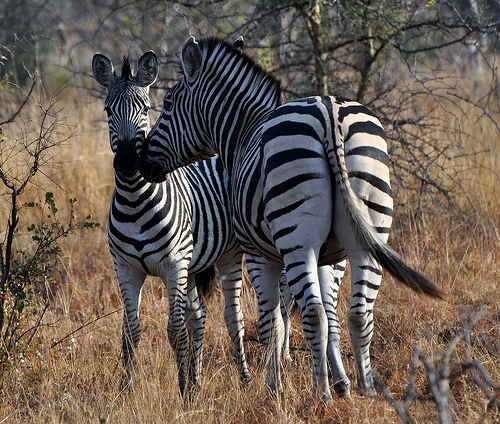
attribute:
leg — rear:
[279, 270, 351, 404]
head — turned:
[124, 50, 248, 183]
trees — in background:
[245, 14, 455, 93]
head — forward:
[105, 53, 152, 187]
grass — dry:
[14, 338, 150, 423]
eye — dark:
[151, 99, 188, 122]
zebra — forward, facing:
[88, 52, 274, 407]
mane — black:
[113, 43, 139, 96]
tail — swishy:
[322, 110, 448, 311]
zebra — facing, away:
[149, 35, 433, 388]